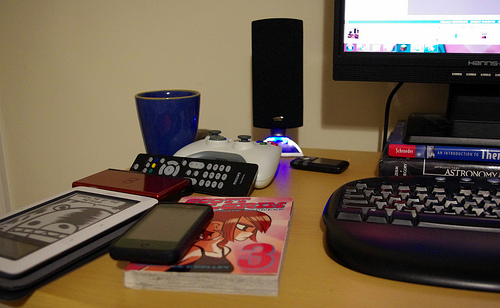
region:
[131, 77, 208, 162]
Blue cup sitting on desk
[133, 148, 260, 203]
Remote control on desk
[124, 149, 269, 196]
Remote control is black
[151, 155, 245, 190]
Remote control has buttons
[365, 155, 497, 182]
Black book on Astronomy on desk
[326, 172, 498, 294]
Keyboard sitting on desk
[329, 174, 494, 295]
Keyboard has black keys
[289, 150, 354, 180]
Cell phone laying on desk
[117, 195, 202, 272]
Cell phone laying on desk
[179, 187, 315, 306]
Book laying on desk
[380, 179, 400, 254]
A keyboard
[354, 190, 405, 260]
A keyboard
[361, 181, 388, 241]
A keyboard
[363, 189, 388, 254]
A keyboard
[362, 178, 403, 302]
A keyboard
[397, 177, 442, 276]
A keyboard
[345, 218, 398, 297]
A keyboard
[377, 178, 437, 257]
A keyboard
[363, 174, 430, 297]
A keyboard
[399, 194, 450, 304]
A keyboard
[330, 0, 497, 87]
black computer monitor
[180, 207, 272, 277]
cartoon girl in a black tank top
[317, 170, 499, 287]
black, ergonomic keyboard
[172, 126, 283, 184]
white xbox controller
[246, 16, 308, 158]
black speaker on a wooden desk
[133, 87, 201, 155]
blue ceramic mug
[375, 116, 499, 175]
stack of books under a monitor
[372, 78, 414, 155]
wiring attached to the monitor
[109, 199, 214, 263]
black smart phone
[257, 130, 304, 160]
glowing speaker base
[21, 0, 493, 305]
several items on a desk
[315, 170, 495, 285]
a black computer keyboard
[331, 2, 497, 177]
a computer monitor resting on a small stack of books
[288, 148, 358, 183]
cell phone on desk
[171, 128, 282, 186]
a video game controller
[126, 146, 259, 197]
a remote control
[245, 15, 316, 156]
a computer speaker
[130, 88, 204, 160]
a blue ceramic mug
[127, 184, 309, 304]
a soft cover book on the desk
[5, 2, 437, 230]
beige colored wall behind the desk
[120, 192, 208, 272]
a black cell phone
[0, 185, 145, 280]
a white computer tablet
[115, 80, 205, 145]
a blue coffee cup on a desk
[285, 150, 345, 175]
a small cell phone laying on a desk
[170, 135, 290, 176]
a white game controller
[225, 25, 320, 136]
a black computer speaker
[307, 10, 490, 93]
a computer monitor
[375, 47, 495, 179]
a monitor sitting on books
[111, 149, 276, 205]
a tv remote